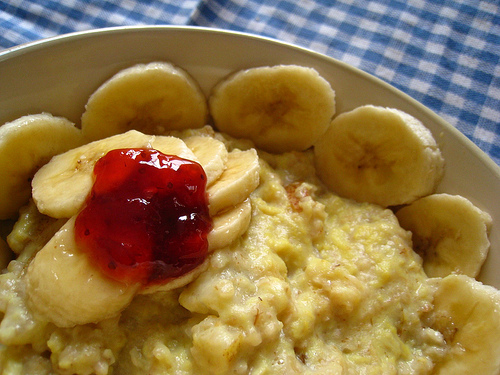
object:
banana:
[207, 64, 337, 155]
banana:
[80, 62, 209, 142]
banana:
[429, 273, 500, 374]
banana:
[315, 104, 446, 207]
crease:
[0, 0, 500, 168]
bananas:
[207, 199, 254, 255]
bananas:
[30, 127, 192, 218]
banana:
[25, 216, 140, 328]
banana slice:
[207, 63, 335, 153]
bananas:
[154, 129, 228, 185]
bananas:
[0, 112, 85, 215]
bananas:
[395, 193, 493, 278]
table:
[0, 0, 500, 375]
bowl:
[0, 25, 500, 375]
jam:
[73, 146, 212, 288]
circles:
[206, 63, 336, 153]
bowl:
[41, 44, 91, 77]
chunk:
[0, 124, 449, 375]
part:
[0, 25, 500, 290]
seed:
[265, 96, 283, 109]